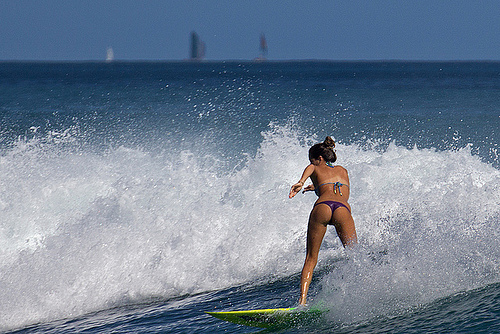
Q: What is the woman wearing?
A: A bikini.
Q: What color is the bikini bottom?
A: Purple.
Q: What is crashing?
A: Large wave.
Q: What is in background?
A: Three sailboats.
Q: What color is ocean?
A: Blue green.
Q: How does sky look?
A: Clear and blue.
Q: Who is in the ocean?
A: Surfer.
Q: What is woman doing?
A: Surfing in ocean.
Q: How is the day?
A: Nice day in the ocean.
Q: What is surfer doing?
A: Catching a large wave.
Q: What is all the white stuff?
A: Water from the waves.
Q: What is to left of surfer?
A: Large wave in water.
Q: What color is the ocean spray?
A: White.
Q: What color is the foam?
A: White.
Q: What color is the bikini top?
A: Blue.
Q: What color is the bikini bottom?
A: Blue.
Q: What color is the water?
A: Blue.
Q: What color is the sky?
A: Blue.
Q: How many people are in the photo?
A: One.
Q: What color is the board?
A: Yellow.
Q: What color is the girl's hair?
A: Brown.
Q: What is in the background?
A: Boats.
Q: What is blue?
A: The sky.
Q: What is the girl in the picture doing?
A: She is surfing the waves.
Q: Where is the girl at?
A: She is in the ocean.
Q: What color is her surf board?
A: Her surf board is yellow.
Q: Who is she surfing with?
A: She is not surfing with anybody.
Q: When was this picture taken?
A: This picture was taken in the day time.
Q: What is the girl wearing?
A: She is wearing a bikini.